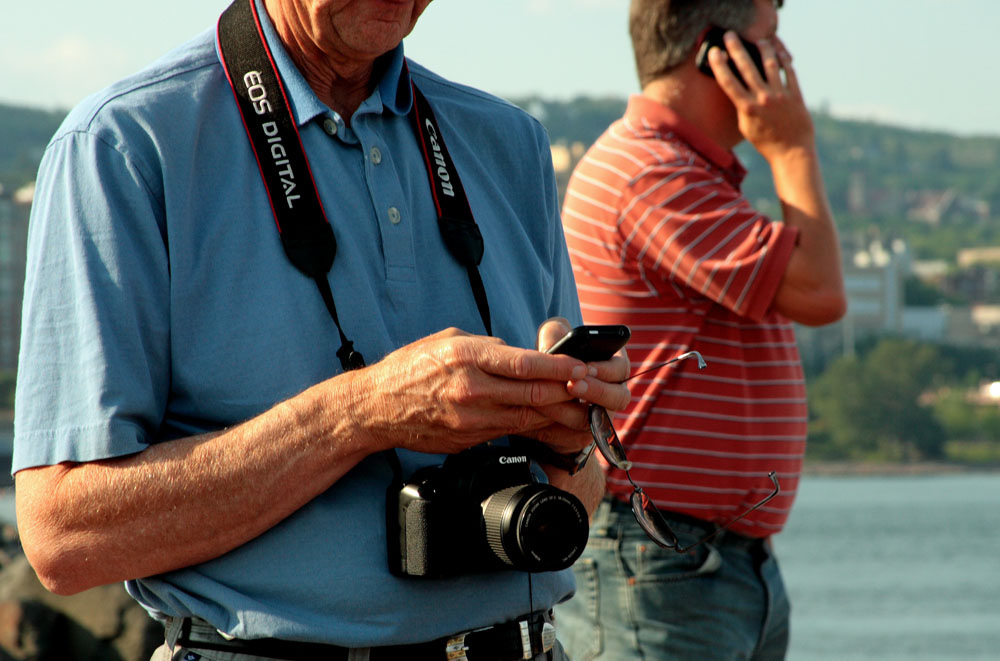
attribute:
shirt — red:
[597, 136, 742, 303]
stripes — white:
[697, 396, 747, 439]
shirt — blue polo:
[18, 45, 578, 621]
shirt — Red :
[553, 101, 834, 531]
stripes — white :
[617, 161, 706, 251]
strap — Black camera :
[211, 3, 574, 597]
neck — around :
[2, 9, 591, 605]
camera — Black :
[306, 303, 635, 621]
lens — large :
[464, 458, 576, 563]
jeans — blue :
[577, 507, 795, 650]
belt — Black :
[353, 600, 540, 658]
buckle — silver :
[458, 600, 561, 649]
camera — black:
[394, 447, 637, 617]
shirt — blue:
[121, 98, 341, 390]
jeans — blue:
[590, 476, 762, 650]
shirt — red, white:
[636, 363, 721, 421]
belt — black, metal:
[218, 590, 567, 657]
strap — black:
[201, 43, 426, 281]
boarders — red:
[200, 50, 290, 248]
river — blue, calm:
[885, 521, 930, 608]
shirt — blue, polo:
[145, 118, 421, 399]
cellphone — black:
[541, 292, 644, 399]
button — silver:
[558, 296, 618, 370]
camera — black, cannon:
[367, 418, 623, 576]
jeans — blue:
[605, 483, 781, 628]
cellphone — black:
[672, 10, 775, 102]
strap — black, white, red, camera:
[189, 50, 314, 273]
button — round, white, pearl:
[336, 118, 396, 174]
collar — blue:
[267, 59, 437, 162]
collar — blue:
[281, 76, 399, 154]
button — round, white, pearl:
[330, 116, 382, 205]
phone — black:
[529, 294, 681, 414]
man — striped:
[638, 27, 819, 516]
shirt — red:
[585, 187, 794, 517]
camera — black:
[354, 392, 617, 573]